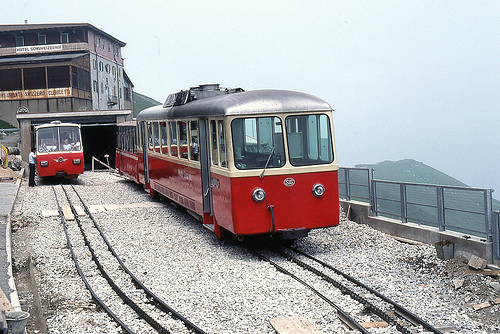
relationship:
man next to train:
[23, 148, 41, 190] [23, 110, 95, 185]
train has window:
[115, 80, 340, 236] [165, 120, 177, 158]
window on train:
[60, 121, 85, 148] [28, 116, 90, 186]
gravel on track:
[30, 181, 456, 333] [36, 182, 178, 332]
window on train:
[211, 121, 227, 168] [79, 35, 380, 279]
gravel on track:
[30, 181, 456, 333] [51, 180, 130, 327]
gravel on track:
[30, 181, 456, 333] [50, 169, 441, 332]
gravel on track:
[30, 181, 456, 333] [254, 237, 452, 332]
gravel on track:
[30, 181, 456, 333] [21, 160, 488, 333]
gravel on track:
[30, 181, 456, 333] [42, 181, 199, 332]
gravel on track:
[30, 181, 456, 333] [51, 172, 205, 332]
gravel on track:
[30, 181, 456, 333] [230, 237, 444, 331]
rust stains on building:
[54, 99, 59, 111] [0, 22, 134, 128]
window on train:
[282, 113, 334, 168] [115, 80, 340, 236]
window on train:
[227, 111, 285, 179] [100, 88, 347, 250]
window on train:
[209, 117, 231, 171] [108, 87, 349, 261]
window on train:
[228, 115, 287, 172] [112, 82, 344, 254]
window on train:
[217, 110, 290, 177] [114, 66, 349, 251]